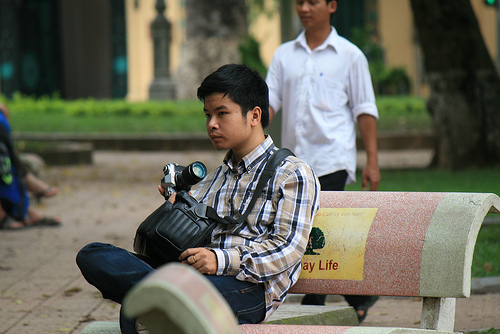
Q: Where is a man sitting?
A: On a bench.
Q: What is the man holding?
A: A camera.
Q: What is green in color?
A: Grass.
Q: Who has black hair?
A: Man sitting.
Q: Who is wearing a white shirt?
A: Man walking.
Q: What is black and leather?
A: A bag.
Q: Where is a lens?
A: On the camera.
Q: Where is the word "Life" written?
A: On a bench.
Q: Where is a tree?
A: In the distance.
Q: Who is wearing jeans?
A: Man holding camera.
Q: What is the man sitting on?
A: Bench.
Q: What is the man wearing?
A: Blue jeans.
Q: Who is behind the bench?
A: Man wearing white shirt.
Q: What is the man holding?
A: Camera.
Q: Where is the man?
A: Park.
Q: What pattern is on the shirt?
A: Plaid.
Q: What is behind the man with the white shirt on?
A: Tree.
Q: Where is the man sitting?
A: Bench.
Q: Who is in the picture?
A: Two men.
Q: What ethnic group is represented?
A: Asian.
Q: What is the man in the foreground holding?
A: A camera.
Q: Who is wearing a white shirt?
A: Walking man.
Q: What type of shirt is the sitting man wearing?
A: Plaid.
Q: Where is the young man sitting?
A: A bench.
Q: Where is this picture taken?
A: Park.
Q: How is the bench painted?
A: Red and green.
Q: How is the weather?
A: Sunny.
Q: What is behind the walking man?
A: Tree.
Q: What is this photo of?
A: A park.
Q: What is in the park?
A: A bench.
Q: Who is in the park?
A: Two men.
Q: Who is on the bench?
A: A man.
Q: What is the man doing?
A: Sitting.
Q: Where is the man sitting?
A: On bench.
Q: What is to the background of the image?
A: Garden.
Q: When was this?
A: Daytime.